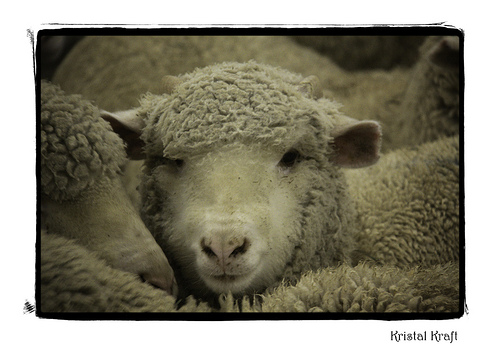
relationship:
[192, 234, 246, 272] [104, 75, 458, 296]
nose on a sheep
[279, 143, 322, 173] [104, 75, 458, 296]
eye of sheep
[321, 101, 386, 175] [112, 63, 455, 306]
ear of sheep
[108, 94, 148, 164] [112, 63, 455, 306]
ear of sheep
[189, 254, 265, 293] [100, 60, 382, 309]
mouth of animal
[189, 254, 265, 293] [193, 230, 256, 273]
mouth under nose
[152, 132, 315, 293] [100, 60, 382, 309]
face of animal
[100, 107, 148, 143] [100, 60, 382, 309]
ear of animal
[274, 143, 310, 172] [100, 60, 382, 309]
eye of animal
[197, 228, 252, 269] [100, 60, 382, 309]
nose of animal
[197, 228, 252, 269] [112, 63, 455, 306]
nose of sheep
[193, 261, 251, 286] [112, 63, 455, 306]
mouth of sheep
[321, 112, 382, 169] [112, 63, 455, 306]
ear of sheep